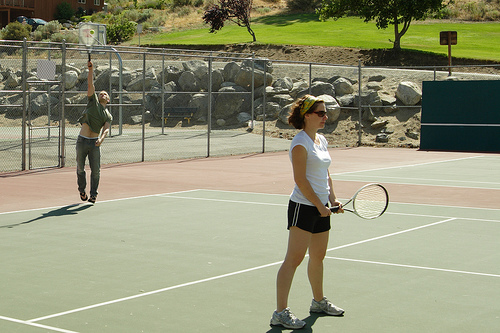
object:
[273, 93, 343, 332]
girl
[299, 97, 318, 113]
headband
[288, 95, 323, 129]
hair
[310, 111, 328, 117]
sunglasses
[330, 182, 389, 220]
racket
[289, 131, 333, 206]
shirt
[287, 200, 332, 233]
shorts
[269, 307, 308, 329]
sneaker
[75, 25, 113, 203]
man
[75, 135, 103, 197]
jeans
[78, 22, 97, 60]
racket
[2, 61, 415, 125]
wall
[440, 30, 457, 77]
sign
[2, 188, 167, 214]
lines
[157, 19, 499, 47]
grass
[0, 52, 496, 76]
roadway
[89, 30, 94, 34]
ball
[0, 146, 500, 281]
court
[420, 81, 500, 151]
wall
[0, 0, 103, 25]
building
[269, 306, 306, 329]
shoes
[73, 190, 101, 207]
in air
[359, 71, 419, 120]
boulders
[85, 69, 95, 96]
arm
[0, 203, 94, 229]
shadow